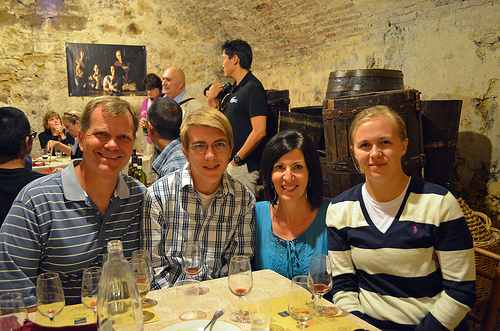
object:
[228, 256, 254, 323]
rock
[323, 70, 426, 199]
barrel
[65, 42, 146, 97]
picture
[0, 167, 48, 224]
shirt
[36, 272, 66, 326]
wine glass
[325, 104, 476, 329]
girl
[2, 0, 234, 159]
wall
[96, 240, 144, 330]
bottle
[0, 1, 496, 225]
wall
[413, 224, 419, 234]
logo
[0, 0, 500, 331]
restaurant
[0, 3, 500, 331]
rock cave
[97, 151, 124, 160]
smiling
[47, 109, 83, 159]
man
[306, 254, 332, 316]
glass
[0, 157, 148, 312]
shirt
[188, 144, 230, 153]
glasses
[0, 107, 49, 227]
man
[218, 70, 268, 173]
shirt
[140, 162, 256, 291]
shirt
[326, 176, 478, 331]
shirt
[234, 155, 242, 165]
watch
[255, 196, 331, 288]
sweater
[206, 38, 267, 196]
man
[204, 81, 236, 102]
camera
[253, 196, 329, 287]
shirt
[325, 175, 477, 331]
sweater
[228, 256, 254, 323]
glass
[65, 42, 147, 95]
poster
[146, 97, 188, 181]
man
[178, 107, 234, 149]
hair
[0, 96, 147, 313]
man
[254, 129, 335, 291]
woman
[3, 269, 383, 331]
table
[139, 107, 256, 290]
boy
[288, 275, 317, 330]
glass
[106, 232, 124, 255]
top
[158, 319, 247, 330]
plate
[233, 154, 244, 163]
wrist